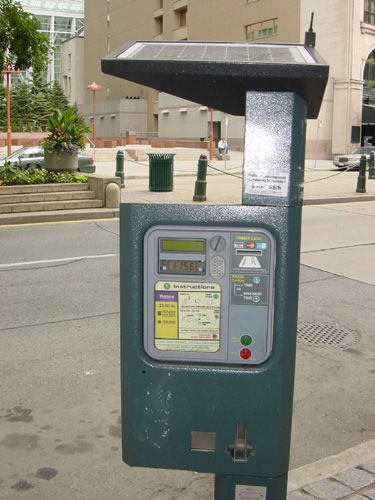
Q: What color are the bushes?
A: Green.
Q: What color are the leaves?
A: Green.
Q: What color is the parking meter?
A: Gray.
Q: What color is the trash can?
A: Green.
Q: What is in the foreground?
A: A parking meter.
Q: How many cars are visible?
A: Two.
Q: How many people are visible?
A: One.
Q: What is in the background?
A: A building.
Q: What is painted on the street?
A: White lines.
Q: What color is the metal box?
A: Green.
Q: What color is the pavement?
A: Gray.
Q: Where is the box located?
A: Outside a building.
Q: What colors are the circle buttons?
A: Green and red.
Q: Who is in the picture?
A: No people in the picture.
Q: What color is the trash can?
A: Green.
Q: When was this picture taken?
A: During the daytime.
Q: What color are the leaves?
A: Green.